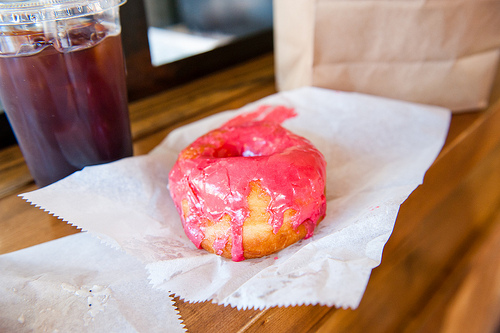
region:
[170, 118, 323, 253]
a thick pink glazed donut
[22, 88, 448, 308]
a white piece of paper for pastry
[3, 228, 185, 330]
a white piece of paper for pastry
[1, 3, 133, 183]
a small plastic cup filled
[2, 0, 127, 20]
a small plastic cup top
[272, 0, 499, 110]
a brown paper bag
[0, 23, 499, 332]
a medium colored wooden table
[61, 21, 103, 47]
ice cube in a cup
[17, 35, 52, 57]
ice cube in a cup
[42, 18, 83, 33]
ice cube in a cup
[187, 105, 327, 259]
icing on the doughnut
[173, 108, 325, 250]
the icing is pink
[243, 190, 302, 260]
the doughnut is brown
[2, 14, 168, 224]
brown liquid in the cup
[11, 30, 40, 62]
ice in the cup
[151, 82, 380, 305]
doughnut on paper wrapper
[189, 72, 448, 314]
the paper wrapper is white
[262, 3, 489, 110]
the paper bag is brown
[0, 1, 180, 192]
cup made of plastic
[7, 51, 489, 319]
table made of wood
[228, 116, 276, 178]
part of a doughnut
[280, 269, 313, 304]
edge of a paper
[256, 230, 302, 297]
part of a paper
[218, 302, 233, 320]
part of a table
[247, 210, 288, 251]
part of a bread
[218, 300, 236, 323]
part of a wood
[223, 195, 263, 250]
edge of a burn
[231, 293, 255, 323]
edge of a paper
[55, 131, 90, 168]
part of a trouser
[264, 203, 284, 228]
part of a cream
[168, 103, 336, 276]
a pink donut over a paper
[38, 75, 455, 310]
a white paper under a donut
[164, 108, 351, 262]
donut is cover with pink frosting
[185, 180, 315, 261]
donut is color brown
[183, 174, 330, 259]
pink frosting spilling on side of donut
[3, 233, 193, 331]
white paper on a table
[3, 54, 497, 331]
a brown wood table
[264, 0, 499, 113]
brown bag of paper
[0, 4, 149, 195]
a cup of tea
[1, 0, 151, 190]
cap is made of plastic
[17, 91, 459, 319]
pink iced doughnut setting on white paper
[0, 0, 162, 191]
soda in clear to go cup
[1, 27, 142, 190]
brown soda pop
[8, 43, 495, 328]
brown wood table with doughnut and drink on it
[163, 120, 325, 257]
doughnut with pink icing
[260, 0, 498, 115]
brown paper lunch bag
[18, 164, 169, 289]
white paper sitting on brown table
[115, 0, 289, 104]
black framed window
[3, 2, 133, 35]
plastic lid on to go cup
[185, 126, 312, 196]
pink doughnut icing